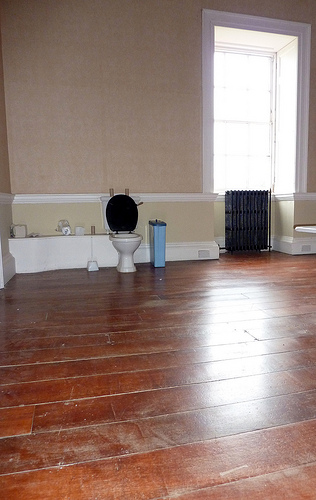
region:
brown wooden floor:
[72, 281, 234, 394]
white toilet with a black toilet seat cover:
[101, 179, 152, 278]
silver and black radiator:
[213, 181, 291, 252]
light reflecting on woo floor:
[178, 279, 274, 440]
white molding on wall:
[18, 186, 76, 213]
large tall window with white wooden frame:
[193, 9, 309, 265]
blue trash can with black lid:
[140, 201, 181, 275]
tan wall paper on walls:
[45, 35, 162, 172]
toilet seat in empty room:
[74, 174, 173, 299]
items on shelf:
[18, 213, 94, 247]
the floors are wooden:
[37, 364, 192, 491]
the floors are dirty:
[25, 358, 177, 479]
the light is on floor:
[190, 348, 271, 445]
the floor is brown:
[19, 353, 227, 495]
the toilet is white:
[107, 195, 135, 277]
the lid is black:
[104, 195, 142, 238]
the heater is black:
[221, 191, 283, 255]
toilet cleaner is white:
[83, 237, 103, 272]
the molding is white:
[8, 190, 216, 203]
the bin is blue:
[145, 218, 172, 269]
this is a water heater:
[213, 176, 283, 277]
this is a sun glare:
[183, 261, 285, 452]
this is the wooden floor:
[3, 301, 142, 437]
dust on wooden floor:
[76, 403, 169, 465]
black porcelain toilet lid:
[101, 178, 142, 235]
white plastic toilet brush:
[80, 225, 106, 282]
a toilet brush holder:
[81, 253, 103, 281]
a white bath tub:
[2, 214, 132, 282]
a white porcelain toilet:
[80, 165, 189, 315]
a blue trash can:
[140, 211, 181, 276]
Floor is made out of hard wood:
[8, 275, 304, 494]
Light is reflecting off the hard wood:
[181, 274, 288, 435]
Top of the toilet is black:
[97, 187, 134, 225]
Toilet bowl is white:
[99, 227, 142, 268]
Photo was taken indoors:
[2, 113, 312, 489]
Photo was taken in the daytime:
[215, 53, 278, 192]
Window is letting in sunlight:
[216, 44, 275, 188]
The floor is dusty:
[35, 402, 171, 474]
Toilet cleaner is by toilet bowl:
[83, 233, 146, 276]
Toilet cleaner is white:
[82, 235, 101, 275]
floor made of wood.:
[227, 276, 272, 291]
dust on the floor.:
[104, 427, 157, 443]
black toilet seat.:
[115, 199, 128, 220]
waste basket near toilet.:
[153, 219, 166, 260]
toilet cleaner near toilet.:
[86, 248, 99, 266]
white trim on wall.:
[2, 256, 10, 273]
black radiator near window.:
[230, 198, 263, 242]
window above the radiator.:
[228, 122, 253, 181]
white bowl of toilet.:
[113, 235, 134, 242]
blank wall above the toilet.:
[80, 115, 173, 165]